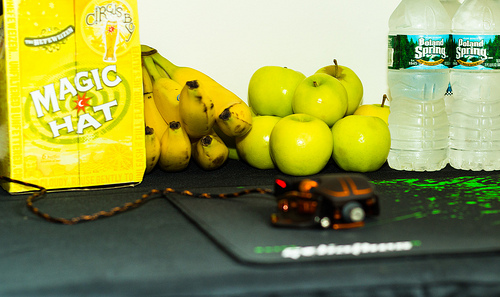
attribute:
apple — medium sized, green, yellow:
[265, 114, 336, 178]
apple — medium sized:
[247, 62, 305, 117]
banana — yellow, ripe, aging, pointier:
[153, 71, 217, 141]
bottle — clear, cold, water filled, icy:
[381, 1, 453, 173]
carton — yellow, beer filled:
[0, 0, 148, 198]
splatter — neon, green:
[374, 163, 499, 225]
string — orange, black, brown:
[3, 174, 276, 233]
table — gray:
[2, 161, 495, 297]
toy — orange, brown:
[268, 161, 377, 238]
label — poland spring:
[451, 32, 499, 74]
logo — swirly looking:
[18, 59, 137, 146]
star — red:
[66, 89, 95, 117]